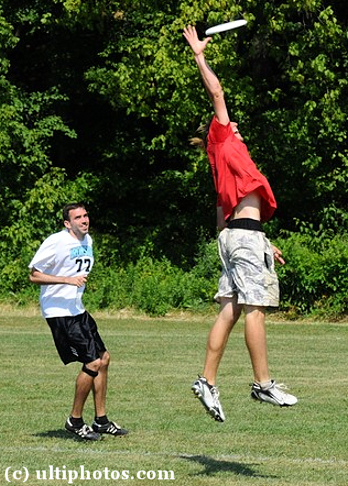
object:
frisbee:
[205, 17, 249, 36]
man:
[27, 205, 129, 442]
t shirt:
[27, 228, 93, 319]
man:
[181, 21, 297, 424]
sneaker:
[64, 417, 101, 441]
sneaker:
[91, 420, 129, 438]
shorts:
[213, 218, 280, 308]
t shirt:
[206, 117, 276, 223]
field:
[1, 313, 347, 484]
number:
[75, 258, 90, 273]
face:
[71, 208, 89, 234]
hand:
[182, 23, 212, 56]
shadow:
[175, 454, 281, 480]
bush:
[179, 229, 347, 321]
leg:
[203, 280, 242, 380]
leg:
[234, 265, 267, 379]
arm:
[195, 52, 229, 128]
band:
[81, 362, 99, 378]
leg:
[59, 321, 103, 414]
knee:
[91, 355, 102, 372]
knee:
[103, 351, 111, 367]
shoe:
[191, 372, 226, 423]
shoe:
[248, 380, 298, 409]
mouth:
[233, 129, 240, 135]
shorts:
[45, 310, 108, 365]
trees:
[0, 3, 100, 295]